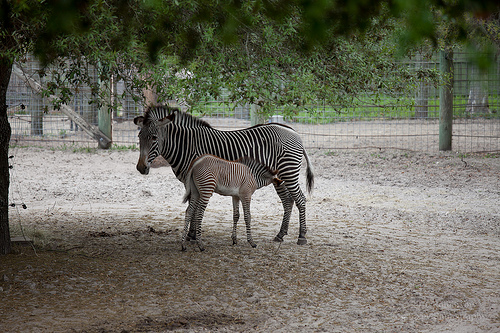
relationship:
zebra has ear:
[132, 102, 314, 252] [158, 113, 176, 124]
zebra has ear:
[132, 102, 314, 252] [131, 115, 145, 123]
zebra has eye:
[120, 98, 334, 235] [143, 130, 162, 146]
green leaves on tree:
[155, 43, 369, 98] [3, 3, 495, 253]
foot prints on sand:
[185, 254, 407, 301] [13, 173, 495, 327]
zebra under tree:
[132, 102, 314, 252] [0, 3, 389, 124]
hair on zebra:
[133, 100, 216, 128] [143, 110, 317, 250]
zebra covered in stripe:
[132, 102, 314, 252] [273, 157, 301, 165]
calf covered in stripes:
[180, 155, 286, 251] [180, 154, 280, 248]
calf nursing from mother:
[180, 155, 286, 251] [131, 100, 315, 247]